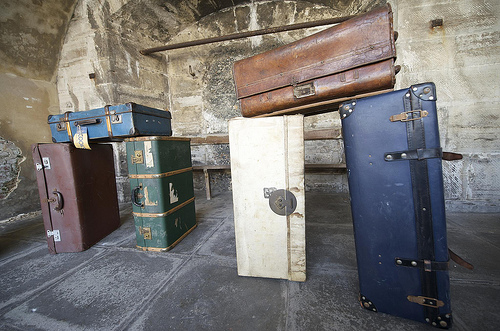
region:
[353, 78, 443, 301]
this is a suitcase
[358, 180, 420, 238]
the suitcase is blue in color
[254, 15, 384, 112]
the suitcase is above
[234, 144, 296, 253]
the suitcase is old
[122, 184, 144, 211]
this is the handle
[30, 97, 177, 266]
the suitcase is three in number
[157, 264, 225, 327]
the floor is cemented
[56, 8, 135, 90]
the wall is rusty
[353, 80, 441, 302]
the suitcase is big in size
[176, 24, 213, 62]
this is a stick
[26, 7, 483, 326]
six old suitcases in a cement room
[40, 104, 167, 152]
blue suitcase on top of two others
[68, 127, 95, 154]
tag on suitcase handle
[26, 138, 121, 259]
red suitcase standing upright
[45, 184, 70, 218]
handle on red suitcase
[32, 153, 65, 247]
two locks on red suitcase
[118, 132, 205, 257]
green suitcase with gold trim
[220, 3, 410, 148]
brown leather suitcase on top of two others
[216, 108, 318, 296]
white suitcase standing upright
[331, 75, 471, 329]
blue suitcase with straps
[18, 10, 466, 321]
suitcases displayed in stone cave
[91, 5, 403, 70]
metal bar across alcove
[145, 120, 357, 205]
wooden bench behind suitcases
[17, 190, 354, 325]
gray and rectangular panels on floor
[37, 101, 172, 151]
blue suitcase with straps and tag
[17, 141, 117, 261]
brown suitcase on its side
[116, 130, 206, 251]
green suitcase with damaged labels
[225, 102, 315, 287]
white trunk with circular latch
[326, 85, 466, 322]
dark blue suitcase with black straps and trim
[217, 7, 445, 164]
brown suitcase on top of white and blue luggage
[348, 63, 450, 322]
A blue luggage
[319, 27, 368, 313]
A blue luggage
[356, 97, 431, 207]
A blue luggage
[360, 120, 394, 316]
A blue luggage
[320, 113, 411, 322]
A blue luggage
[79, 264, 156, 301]
this is the floor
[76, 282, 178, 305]
the floor is made of cement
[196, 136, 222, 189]
this is a bench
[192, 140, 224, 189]
the bench is wooden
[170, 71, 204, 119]
this is a wall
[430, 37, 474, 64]
the wall is made of stone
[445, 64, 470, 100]
the stone is grey in color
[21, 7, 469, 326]
these are several suitcases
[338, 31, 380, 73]
the suitcase is closed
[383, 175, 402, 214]
the suitcase is blue in color